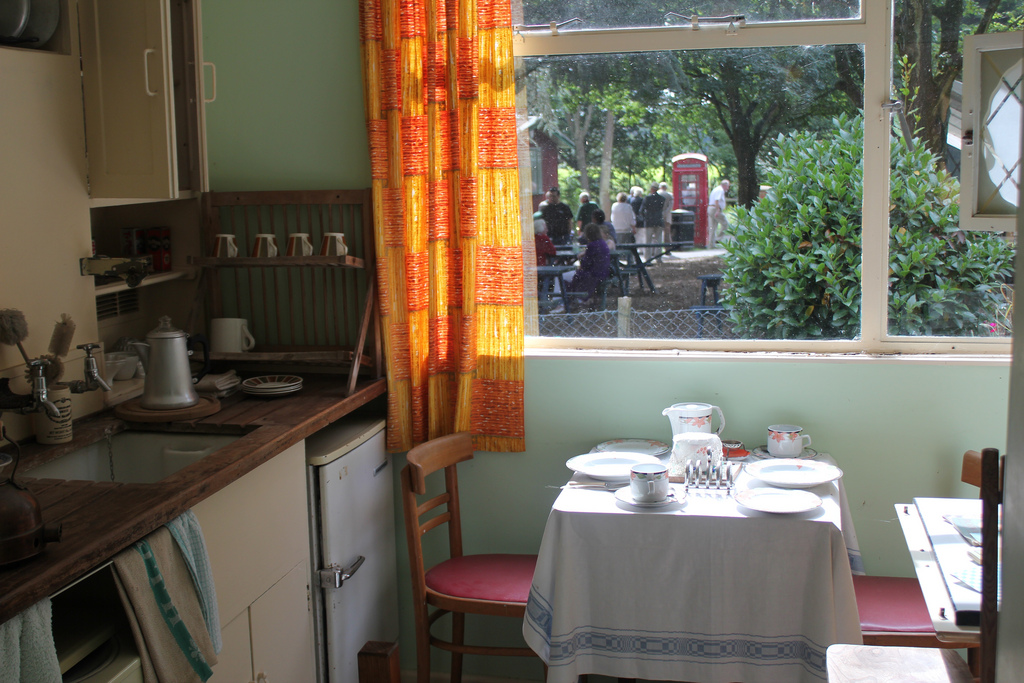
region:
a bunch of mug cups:
[201, 212, 363, 279]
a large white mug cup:
[210, 291, 264, 349]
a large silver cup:
[132, 323, 206, 418]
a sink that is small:
[41, 411, 206, 500]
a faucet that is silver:
[63, 333, 121, 398]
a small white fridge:
[303, 453, 406, 650]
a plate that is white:
[568, 440, 646, 495]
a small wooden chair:
[385, 420, 547, 652]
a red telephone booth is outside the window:
[661, 146, 715, 258]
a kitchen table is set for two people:
[525, 388, 854, 679]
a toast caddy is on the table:
[682, 440, 739, 494]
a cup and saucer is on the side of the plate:
[599, 455, 686, 509]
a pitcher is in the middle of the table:
[664, 397, 715, 470]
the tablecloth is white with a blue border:
[524, 437, 866, 678]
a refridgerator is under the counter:
[318, 414, 405, 680]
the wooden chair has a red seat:
[397, 426, 544, 671]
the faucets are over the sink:
[24, 334, 139, 508]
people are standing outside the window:
[512, 152, 740, 355]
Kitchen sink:
[13, 402, 263, 500]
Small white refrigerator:
[304, 401, 425, 680]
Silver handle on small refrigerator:
[317, 541, 376, 598]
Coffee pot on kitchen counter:
[127, 303, 207, 417]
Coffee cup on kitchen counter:
[198, 301, 265, 371]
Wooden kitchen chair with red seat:
[386, 416, 563, 676]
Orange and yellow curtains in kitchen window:
[358, 7, 542, 469]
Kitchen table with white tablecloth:
[513, 443, 867, 677]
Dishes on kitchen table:
[558, 391, 850, 528]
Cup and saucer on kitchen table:
[608, 452, 688, 516]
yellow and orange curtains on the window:
[360, 15, 535, 442]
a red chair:
[389, 443, 555, 650]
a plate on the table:
[575, 446, 643, 470]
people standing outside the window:
[539, 187, 666, 264]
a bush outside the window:
[736, 141, 942, 291]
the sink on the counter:
[41, 420, 209, 485]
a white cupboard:
[84, 16, 179, 181]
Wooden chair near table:
[400, 426, 547, 680]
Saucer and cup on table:
[612, 459, 683, 513]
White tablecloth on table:
[515, 440, 851, 678]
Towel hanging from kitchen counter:
[106, 502, 228, 676]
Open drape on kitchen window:
[359, 0, 528, 459]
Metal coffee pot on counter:
[128, 323, 201, 409]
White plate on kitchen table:
[558, 449, 672, 479]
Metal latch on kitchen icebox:
[318, 550, 372, 589]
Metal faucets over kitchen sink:
[5, 336, 107, 423]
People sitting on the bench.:
[549, 195, 620, 307]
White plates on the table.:
[556, 427, 661, 484]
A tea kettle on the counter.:
[123, 313, 213, 422]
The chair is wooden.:
[395, 437, 523, 679]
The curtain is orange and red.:
[357, 6, 547, 472]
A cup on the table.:
[762, 411, 808, 460]